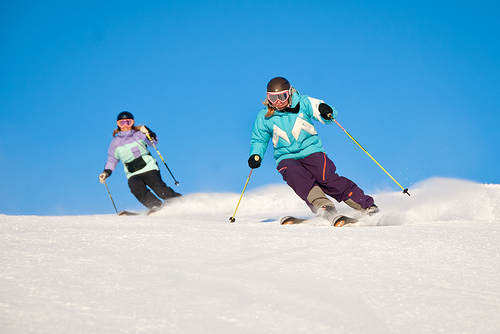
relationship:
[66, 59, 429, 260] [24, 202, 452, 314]
skiers going down hill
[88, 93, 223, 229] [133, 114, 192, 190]
skier holding pole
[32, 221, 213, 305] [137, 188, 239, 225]
snow from skis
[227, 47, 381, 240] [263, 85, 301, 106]
he wearing goggles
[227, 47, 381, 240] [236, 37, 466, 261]
skiier on right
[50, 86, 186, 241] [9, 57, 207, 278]
skiier on left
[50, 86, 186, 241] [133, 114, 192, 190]
woman with pole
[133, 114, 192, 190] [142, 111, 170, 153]
pole in hand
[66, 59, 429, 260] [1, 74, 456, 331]
skiiers going down hill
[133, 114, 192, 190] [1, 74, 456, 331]
poles in photo